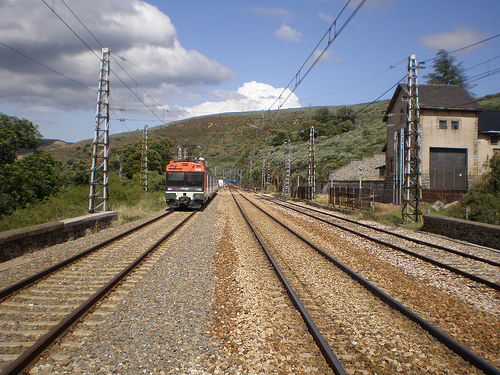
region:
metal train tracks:
[226, 234, 484, 362]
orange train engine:
[158, 141, 213, 217]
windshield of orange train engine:
[162, 170, 206, 187]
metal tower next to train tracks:
[83, 40, 118, 225]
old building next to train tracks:
[379, 55, 486, 223]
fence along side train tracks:
[319, 177, 378, 215]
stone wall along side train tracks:
[415, 197, 496, 252]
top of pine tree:
[413, 31, 478, 96]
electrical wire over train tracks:
[31, 2, 195, 149]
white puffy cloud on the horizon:
[160, 72, 304, 121]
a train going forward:
[156, 152, 225, 217]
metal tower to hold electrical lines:
[81, 38, 119, 215]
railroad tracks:
[227, 171, 498, 373]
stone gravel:
[96, 290, 274, 372]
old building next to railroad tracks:
[320, 60, 498, 254]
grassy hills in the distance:
[0, 90, 377, 202]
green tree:
[1, 107, 52, 213]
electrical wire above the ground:
[280, 0, 384, 102]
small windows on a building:
[433, 115, 464, 134]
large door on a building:
[425, 141, 476, 196]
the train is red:
[161, 162, 219, 212]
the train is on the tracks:
[162, 160, 219, 211]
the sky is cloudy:
[4, 0, 499, 140]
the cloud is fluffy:
[171, 84, 301, 121]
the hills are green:
[0, 92, 499, 227]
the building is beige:
[383, 82, 480, 202]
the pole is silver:
[82, 46, 111, 218]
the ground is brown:
[1, 184, 497, 374]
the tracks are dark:
[0, 197, 498, 371]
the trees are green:
[1, 117, 58, 214]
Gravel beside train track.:
[107, 246, 184, 333]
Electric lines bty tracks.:
[247, 121, 312, 208]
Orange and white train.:
[143, 157, 223, 277]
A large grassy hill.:
[219, 102, 295, 201]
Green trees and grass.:
[2, 113, 102, 208]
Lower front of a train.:
[167, 190, 199, 203]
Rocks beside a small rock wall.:
[405, 186, 494, 227]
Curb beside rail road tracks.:
[1, 197, 123, 269]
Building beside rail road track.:
[276, 110, 472, 292]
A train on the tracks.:
[77, 133, 242, 321]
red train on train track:
[161, 150, 221, 212]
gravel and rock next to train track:
[146, 281, 191, 334]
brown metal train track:
[3, 219, 178, 371]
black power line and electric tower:
[9, 19, 174, 134]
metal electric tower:
[88, 40, 114, 213]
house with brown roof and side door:
[382, 79, 496, 192]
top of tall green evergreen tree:
[426, 46, 478, 98]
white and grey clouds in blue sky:
[136, 25, 296, 107]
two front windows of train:
[165, 171, 204, 191]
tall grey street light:
[383, 56, 421, 71]